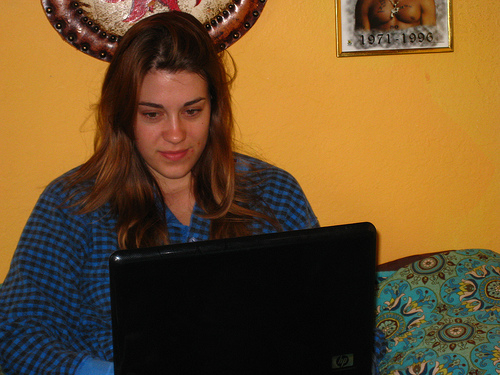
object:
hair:
[38, 9, 285, 251]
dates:
[357, 31, 434, 45]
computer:
[108, 221, 380, 374]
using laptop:
[0, 7, 388, 375]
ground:
[423, 144, 445, 179]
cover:
[373, 247, 499, 374]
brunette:
[0, 10, 389, 374]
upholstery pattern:
[376, 248, 499, 374]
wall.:
[0, 0, 499, 287]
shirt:
[0, 149, 388, 375]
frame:
[331, 0, 455, 58]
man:
[353, 0, 436, 34]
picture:
[332, 0, 454, 59]